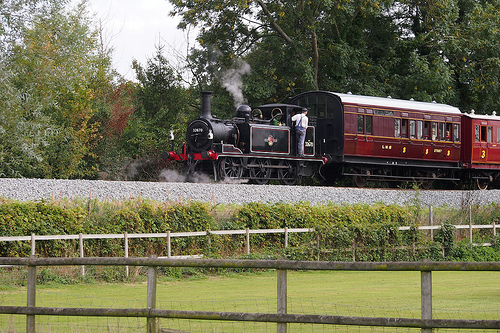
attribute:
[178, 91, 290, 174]
train — black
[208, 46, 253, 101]
smoke — coming 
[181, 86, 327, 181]
engine — black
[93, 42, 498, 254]
engine — black, red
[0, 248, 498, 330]
fence — wooden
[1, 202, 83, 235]
shrub — green, small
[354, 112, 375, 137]
windows — dark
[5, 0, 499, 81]
sky — white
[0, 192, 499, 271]
weeds — covered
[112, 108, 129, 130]
leaves — red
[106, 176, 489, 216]
gravel — gray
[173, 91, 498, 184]
train — black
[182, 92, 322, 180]
engine — black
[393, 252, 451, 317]
fence — small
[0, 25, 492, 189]
trees — beside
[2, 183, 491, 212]
rocks — gray, small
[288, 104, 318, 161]
man — looking backwards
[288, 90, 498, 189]
train cars — red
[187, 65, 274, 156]
steam engine — old fashioned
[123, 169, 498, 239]
gravel — gray 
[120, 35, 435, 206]
train — black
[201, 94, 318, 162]
train engine — black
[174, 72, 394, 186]
front — red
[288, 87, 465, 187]
passenger car — dark red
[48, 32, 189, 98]
sky — white, overcast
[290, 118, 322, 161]
overalls — blue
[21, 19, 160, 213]
tree — green, leafy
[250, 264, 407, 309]
land — flat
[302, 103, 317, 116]
hat — gray